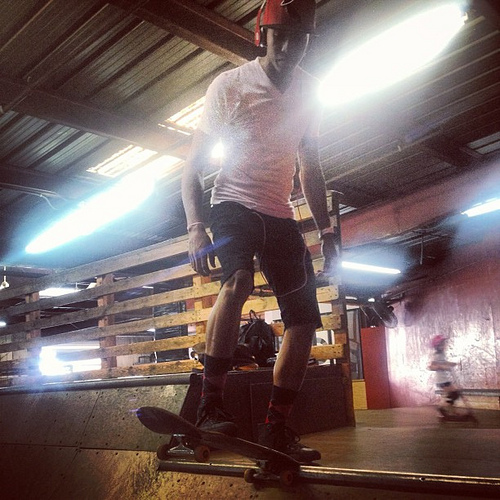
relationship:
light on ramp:
[23, 176, 156, 257] [107, 419, 490, 490]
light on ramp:
[23, 176, 156, 257] [62, 385, 445, 497]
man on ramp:
[136, 0, 339, 484] [39, 316, 357, 487]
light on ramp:
[23, 176, 156, 257] [40, 341, 415, 492]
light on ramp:
[23, 176, 156, 257] [59, 346, 439, 489]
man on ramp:
[136, 0, 339, 484] [26, 237, 420, 492]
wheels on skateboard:
[148, 430, 261, 490] [116, 397, 343, 484]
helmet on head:
[244, 0, 306, 27] [246, 28, 300, 82]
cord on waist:
[232, 210, 284, 260] [175, 161, 357, 256]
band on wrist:
[187, 222, 204, 233] [289, 208, 341, 253]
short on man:
[208, 200, 324, 332] [135, 35, 415, 410]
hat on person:
[251, 3, 322, 38] [144, 70, 365, 454]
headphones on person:
[245, 16, 283, 55] [156, 20, 373, 416]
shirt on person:
[195, 56, 323, 220] [108, 30, 411, 491]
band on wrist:
[175, 219, 218, 246] [165, 204, 254, 285]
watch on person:
[306, 223, 365, 250] [155, 24, 404, 463]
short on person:
[208, 200, 324, 332] [141, 19, 388, 439]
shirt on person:
[188, 68, 343, 239] [155, 24, 404, 463]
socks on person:
[155, 358, 325, 487] [161, 22, 414, 390]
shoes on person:
[138, 381, 268, 453] [167, 14, 385, 462]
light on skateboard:
[23, 176, 156, 257] [125, 393, 289, 489]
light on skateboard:
[23, 176, 156, 257] [138, 390, 277, 470]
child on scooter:
[415, 324, 474, 388] [435, 340, 484, 439]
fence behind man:
[0, 190, 350, 389] [238, 22, 368, 429]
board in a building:
[135, 405, 302, 487] [15, 17, 456, 466]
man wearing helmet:
[209, 18, 367, 315] [238, 0, 360, 41]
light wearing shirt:
[23, 176, 156, 257] [215, 55, 365, 245]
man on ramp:
[136, 0, 339, 484] [25, 359, 392, 479]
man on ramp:
[136, 0, 339, 484] [33, 357, 314, 467]